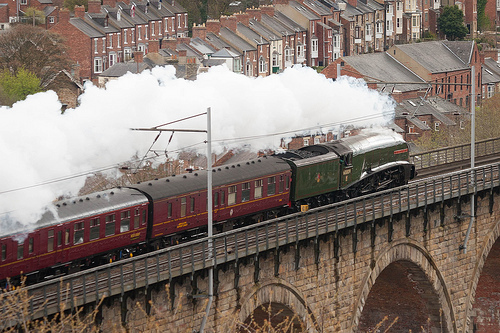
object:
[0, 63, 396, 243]
smoke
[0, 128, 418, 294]
train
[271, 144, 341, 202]
car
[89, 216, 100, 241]
windows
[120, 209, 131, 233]
windows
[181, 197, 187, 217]
windows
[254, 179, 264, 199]
windows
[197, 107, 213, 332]
pole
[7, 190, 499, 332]
bridge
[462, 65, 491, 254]
pole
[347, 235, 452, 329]
arch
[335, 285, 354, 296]
bricks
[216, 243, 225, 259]
train tracks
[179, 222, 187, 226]
words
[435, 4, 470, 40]
tree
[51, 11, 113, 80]
building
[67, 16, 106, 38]
roof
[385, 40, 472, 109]
houses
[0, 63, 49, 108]
trees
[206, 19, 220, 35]
chimneys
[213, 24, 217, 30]
bricks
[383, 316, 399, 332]
plants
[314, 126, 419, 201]
engine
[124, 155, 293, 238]
car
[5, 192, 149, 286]
car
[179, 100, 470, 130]
cables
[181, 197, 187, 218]
shades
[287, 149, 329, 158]
coal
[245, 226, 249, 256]
railings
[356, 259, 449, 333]
river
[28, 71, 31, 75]
leaves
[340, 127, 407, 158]
snow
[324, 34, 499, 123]
buildings